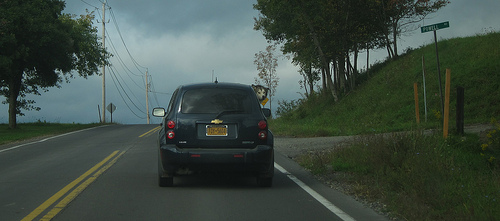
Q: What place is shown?
A: It is a road.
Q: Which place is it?
A: It is a road.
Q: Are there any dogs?
A: Yes, there is a dog.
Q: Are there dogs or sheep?
A: Yes, there is a dog.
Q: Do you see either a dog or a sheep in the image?
A: Yes, there is a dog.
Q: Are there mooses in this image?
A: No, there are no mooses.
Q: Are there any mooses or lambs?
A: No, there are no mooses or lambs.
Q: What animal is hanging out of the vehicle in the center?
A: The dog is hanging out of the car.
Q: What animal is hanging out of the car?
A: The dog is hanging out of the car.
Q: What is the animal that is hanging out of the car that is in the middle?
A: The animal is a dog.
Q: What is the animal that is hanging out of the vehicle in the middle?
A: The animal is a dog.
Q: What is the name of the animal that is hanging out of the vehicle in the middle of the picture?
A: The animal is a dog.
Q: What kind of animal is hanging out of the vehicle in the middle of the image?
A: The animal is a dog.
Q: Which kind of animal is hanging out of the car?
A: The animal is a dog.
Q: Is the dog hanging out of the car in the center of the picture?
A: Yes, the dog is hanging out of the car.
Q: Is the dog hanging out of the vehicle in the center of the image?
A: Yes, the dog is hanging out of the car.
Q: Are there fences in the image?
A: No, there are no fences.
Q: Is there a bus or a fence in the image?
A: No, there are no fences or buses.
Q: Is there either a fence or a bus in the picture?
A: No, there are no fences or buses.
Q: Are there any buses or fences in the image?
A: No, there are no fences or buses.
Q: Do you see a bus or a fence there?
A: No, there are no fences or buses.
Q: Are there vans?
A: No, there are no vans.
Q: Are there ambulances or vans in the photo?
A: No, there are no vans or ambulances.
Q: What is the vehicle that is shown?
A: The vehicle is a car.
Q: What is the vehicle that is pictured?
A: The vehicle is a car.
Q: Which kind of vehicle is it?
A: The vehicle is a car.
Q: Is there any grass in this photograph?
A: Yes, there is grass.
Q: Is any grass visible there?
A: Yes, there is grass.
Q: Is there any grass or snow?
A: Yes, there is grass.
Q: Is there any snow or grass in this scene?
A: Yes, there is grass.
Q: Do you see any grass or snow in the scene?
A: Yes, there is grass.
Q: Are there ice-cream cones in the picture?
A: No, there are no ice-cream cones.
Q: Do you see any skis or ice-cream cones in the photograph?
A: No, there are no ice-cream cones or skis.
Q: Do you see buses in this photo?
A: No, there are no buses.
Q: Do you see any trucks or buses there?
A: No, there are no buses or trucks.